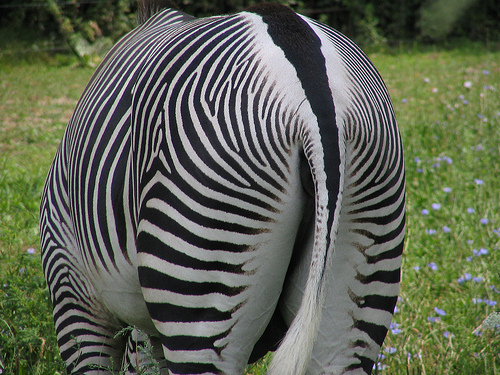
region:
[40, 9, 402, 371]
the zebra is black and white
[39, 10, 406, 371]
the zebra has stripes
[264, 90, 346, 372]
the zebra has a black and white tail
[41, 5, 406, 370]
the zebras head is facing down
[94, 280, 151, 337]
the zebra has a white belly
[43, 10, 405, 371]
the zebra is outdoors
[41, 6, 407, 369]
the zebra is on the grass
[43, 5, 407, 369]
the zebra is large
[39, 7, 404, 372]
the zebras backside is facing the camera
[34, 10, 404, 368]
the animal is on the grass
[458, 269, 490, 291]
Purple flowers in a feild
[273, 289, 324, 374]
The hairs at the end of the zebras tail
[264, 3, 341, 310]
The stripe going down the zebras butt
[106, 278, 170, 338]
The part of the zebras belly with no stripes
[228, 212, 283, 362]
The part of the zebras leg with no stripes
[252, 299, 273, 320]
The veins on the zebras leg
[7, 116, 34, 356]
The grass feild around the zebra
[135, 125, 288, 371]
The stripes on the zebras leg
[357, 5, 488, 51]
The bushes in front of zebra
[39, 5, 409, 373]
The zebra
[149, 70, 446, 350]
the butt of a zebra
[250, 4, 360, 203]
dark black stripe leading to tail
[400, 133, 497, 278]
little blue wild flowers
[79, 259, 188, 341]
white underbelly of zebra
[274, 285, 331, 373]
white hair on tail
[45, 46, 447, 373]
a white zebra with black stripes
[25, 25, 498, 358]
a zebra in a field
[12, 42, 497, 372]
a grass field with wild flowers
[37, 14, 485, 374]
a zebra stopping to eat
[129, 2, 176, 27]
a small part of the zebra's mane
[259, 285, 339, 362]
the tip of the tail is white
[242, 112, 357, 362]
the tail is long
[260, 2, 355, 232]
the back of the stripe is wide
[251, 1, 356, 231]
the stripe is wide and black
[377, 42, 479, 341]
the grass is high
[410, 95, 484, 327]
flowers are in the grass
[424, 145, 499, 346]
the flowers are purple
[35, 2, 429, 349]
the zebra is in the grass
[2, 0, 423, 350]
the zebra is grazing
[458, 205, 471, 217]
part of a garden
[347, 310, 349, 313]
part of a zebra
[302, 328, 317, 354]
part of a tail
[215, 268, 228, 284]
part of a zebra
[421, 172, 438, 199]
part of a garden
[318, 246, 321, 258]
edge of a tail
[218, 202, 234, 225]
back of a zebra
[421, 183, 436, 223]
part of a field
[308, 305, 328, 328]
part of a tail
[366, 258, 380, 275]
side of a zebra